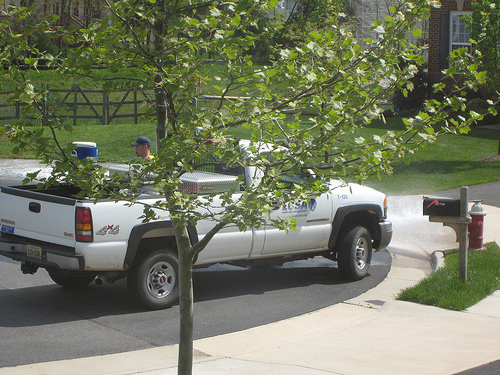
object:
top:
[459, 186, 468, 219]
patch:
[395, 241, 499, 312]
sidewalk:
[359, 311, 496, 369]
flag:
[423, 198, 448, 209]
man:
[134, 136, 161, 174]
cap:
[131, 135, 152, 147]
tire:
[126, 249, 181, 309]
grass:
[415, 282, 464, 306]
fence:
[0, 80, 157, 127]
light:
[75, 223, 92, 230]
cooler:
[71, 141, 99, 174]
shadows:
[390, 159, 496, 176]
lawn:
[384, 123, 497, 196]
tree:
[1, 5, 500, 373]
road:
[10, 278, 314, 368]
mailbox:
[422, 195, 461, 215]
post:
[458, 186, 470, 283]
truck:
[0, 136, 393, 312]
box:
[95, 160, 241, 195]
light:
[74, 207, 93, 225]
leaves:
[303, 70, 317, 84]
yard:
[33, 63, 368, 145]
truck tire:
[337, 223, 372, 282]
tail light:
[75, 235, 94, 243]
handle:
[29, 202, 42, 213]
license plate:
[27, 244, 43, 260]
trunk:
[178, 265, 194, 372]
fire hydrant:
[468, 199, 487, 248]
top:
[468, 199, 487, 216]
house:
[267, 0, 500, 125]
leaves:
[470, 69, 486, 87]